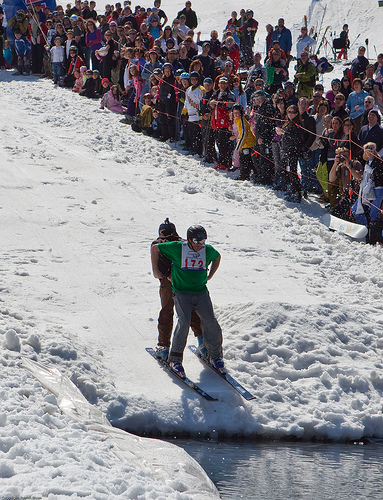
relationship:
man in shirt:
[150, 223, 225, 376] [156, 240, 218, 294]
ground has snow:
[1, 63, 381, 498] [2, 66, 381, 495]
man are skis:
[150, 225, 222, 379] [144, 346, 218, 403]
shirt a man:
[158, 241, 221, 295] [150, 223, 225, 376]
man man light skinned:
[150, 225, 222, 379] [151, 305, 261, 454]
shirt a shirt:
[158, 241, 221, 295] [158, 241, 221, 295]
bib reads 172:
[179, 241, 206, 266] [184, 257, 206, 268]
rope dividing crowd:
[227, 112, 357, 145] [4, 5, 381, 203]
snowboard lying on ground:
[296, 194, 379, 254] [2, 192, 371, 409]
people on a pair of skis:
[138, 209, 251, 346] [137, 341, 258, 399]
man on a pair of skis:
[150, 225, 222, 379] [142, 342, 258, 402]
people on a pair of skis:
[149, 217, 209, 360] [142, 342, 258, 402]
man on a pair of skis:
[150, 225, 222, 379] [137, 330, 253, 408]